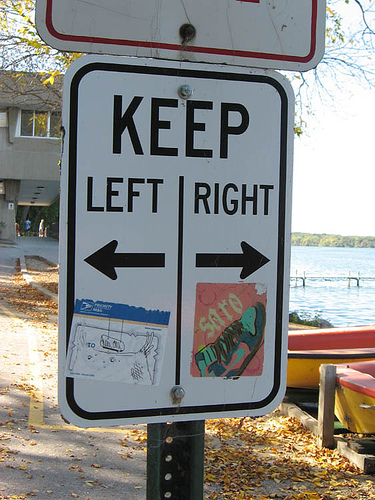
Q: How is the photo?
A: Clear.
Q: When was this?
A: Daytime.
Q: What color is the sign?
A: White.